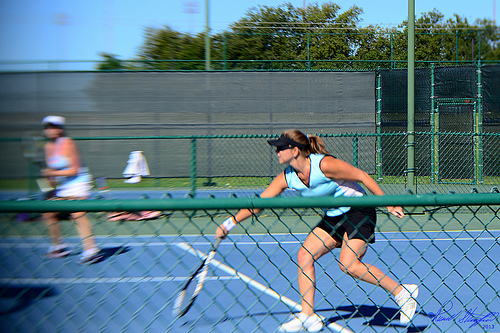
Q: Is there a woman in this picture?
A: Yes, there is a woman.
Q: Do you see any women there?
A: Yes, there is a woman.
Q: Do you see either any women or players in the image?
A: Yes, there is a woman.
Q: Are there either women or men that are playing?
A: Yes, the woman is playing.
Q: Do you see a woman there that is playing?
A: Yes, there is a woman that is playing.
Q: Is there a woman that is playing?
A: Yes, there is a woman that is playing.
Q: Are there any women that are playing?
A: Yes, there is a woman that is playing.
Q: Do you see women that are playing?
A: Yes, there is a woman that is playing.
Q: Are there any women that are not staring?
A: Yes, there is a woman that is playing.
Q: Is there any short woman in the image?
A: Yes, there is a short woman.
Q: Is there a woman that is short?
A: Yes, there is a woman that is short.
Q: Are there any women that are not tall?
A: Yes, there is a short woman.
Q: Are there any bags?
A: No, there are no bags.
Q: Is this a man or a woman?
A: This is a woman.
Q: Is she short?
A: Yes, the woman is short.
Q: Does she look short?
A: Yes, the woman is short.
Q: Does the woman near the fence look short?
A: Yes, the woman is short.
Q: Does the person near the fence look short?
A: Yes, the woman is short.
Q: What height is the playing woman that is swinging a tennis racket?
A: The woman is short.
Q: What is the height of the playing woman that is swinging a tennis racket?
A: The woman is short.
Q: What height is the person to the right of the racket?
A: The woman is short.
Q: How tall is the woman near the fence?
A: The woman is short.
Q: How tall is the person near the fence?
A: The woman is short.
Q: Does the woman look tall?
A: No, the woman is short.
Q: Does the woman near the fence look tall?
A: No, the woman is short.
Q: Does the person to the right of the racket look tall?
A: No, the woman is short.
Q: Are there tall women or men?
A: No, there is a woman but she is short.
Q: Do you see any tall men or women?
A: No, there is a woman but she is short.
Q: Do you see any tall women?
A: No, there is a woman but she is short.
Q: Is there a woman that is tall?
A: No, there is a woman but she is short.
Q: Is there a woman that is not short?
A: No, there is a woman but she is short.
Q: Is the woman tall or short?
A: The woman is short.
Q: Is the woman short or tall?
A: The woman is short.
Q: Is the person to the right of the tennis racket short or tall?
A: The woman is short.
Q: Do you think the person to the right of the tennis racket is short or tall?
A: The woman is short.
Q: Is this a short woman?
A: Yes, this is a short woman.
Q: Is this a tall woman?
A: No, this is a short woman.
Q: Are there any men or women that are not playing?
A: No, there is a woman but she is playing.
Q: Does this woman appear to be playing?
A: Yes, the woman is playing.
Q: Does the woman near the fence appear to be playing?
A: Yes, the woman is playing.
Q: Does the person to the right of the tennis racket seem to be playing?
A: Yes, the woman is playing.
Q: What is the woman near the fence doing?
A: The woman is playing.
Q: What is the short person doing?
A: The woman is playing.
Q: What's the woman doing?
A: The woman is playing.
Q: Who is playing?
A: The woman is playing.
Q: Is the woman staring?
A: No, the woman is playing.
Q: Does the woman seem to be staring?
A: No, the woman is playing.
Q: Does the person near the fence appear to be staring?
A: No, the woman is playing.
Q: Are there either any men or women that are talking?
A: No, there is a woman but she is playing.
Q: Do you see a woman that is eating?
A: No, there is a woman but she is playing.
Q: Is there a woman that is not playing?
A: No, there is a woman but she is playing.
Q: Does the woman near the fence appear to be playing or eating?
A: The woman is playing.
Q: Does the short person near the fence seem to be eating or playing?
A: The woman is playing.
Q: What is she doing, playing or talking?
A: The woman is playing.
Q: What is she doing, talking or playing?
A: The woman is playing.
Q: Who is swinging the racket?
A: The woman is swinging the racket.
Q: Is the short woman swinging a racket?
A: Yes, the woman is swinging a racket.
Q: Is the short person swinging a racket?
A: Yes, the woman is swinging a racket.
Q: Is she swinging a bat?
A: No, the woman is swinging a racket.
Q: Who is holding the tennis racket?
A: The woman is holding the tennis racket.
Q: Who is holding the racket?
A: The woman is holding the tennis racket.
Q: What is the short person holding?
A: The woman is holding the tennis racket.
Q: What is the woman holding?
A: The woman is holding the tennis racket.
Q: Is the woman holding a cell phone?
A: No, the woman is holding the racket.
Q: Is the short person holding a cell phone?
A: No, the woman is holding the racket.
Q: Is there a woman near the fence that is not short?
A: Yes, there is a woman near the fence.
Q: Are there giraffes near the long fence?
A: No, there is a woman near the fence.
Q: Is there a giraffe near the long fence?
A: No, there is a woman near the fence.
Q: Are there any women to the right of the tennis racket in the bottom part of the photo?
A: Yes, there is a woman to the right of the racket.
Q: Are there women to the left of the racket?
A: No, the woman is to the right of the racket.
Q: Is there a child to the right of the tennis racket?
A: No, there is a woman to the right of the tennis racket.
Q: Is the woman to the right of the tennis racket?
A: Yes, the woman is to the right of the tennis racket.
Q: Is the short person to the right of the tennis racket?
A: Yes, the woman is to the right of the tennis racket.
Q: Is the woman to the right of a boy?
A: No, the woman is to the right of the tennis racket.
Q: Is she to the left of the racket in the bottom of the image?
A: No, the woman is to the right of the tennis racket.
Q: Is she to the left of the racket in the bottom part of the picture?
A: No, the woman is to the right of the tennis racket.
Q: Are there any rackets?
A: Yes, there is a racket.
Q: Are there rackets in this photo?
A: Yes, there is a racket.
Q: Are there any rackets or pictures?
A: Yes, there is a racket.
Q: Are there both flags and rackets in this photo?
A: No, there is a racket but no flags.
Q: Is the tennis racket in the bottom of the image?
A: Yes, the tennis racket is in the bottom of the image.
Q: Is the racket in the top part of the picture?
A: No, the racket is in the bottom of the image.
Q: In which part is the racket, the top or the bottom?
A: The racket is in the bottom of the image.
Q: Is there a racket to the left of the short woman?
A: Yes, there is a racket to the left of the woman.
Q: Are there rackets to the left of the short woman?
A: Yes, there is a racket to the left of the woman.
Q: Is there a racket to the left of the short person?
A: Yes, there is a racket to the left of the woman.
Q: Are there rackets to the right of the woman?
A: No, the racket is to the left of the woman.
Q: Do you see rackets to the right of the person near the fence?
A: No, the racket is to the left of the woman.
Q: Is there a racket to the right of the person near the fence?
A: No, the racket is to the left of the woman.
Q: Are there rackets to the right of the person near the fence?
A: No, the racket is to the left of the woman.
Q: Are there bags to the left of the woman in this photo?
A: No, there is a racket to the left of the woman.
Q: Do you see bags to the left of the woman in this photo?
A: No, there is a racket to the left of the woman.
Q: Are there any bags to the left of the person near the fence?
A: No, there is a racket to the left of the woman.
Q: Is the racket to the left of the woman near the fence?
A: Yes, the racket is to the left of the woman.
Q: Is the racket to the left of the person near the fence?
A: Yes, the racket is to the left of the woman.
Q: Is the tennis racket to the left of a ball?
A: No, the tennis racket is to the left of the woman.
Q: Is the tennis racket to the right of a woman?
A: No, the tennis racket is to the left of a woman.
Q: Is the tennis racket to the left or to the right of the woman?
A: The tennis racket is to the left of the woman.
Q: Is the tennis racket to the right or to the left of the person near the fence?
A: The tennis racket is to the left of the woman.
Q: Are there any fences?
A: Yes, there is a fence.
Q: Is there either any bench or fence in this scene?
A: Yes, there is a fence.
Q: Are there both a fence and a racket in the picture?
A: Yes, there are both a fence and a racket.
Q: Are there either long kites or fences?
A: Yes, there is a long fence.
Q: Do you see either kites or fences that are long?
A: Yes, the fence is long.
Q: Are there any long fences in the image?
A: Yes, there is a long fence.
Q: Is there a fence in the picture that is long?
A: Yes, there is a fence that is long.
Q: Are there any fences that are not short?
A: Yes, there is a long fence.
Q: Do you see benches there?
A: No, there are no benches.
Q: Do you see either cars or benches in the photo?
A: No, there are no benches or cars.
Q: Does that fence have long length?
A: Yes, the fence is long.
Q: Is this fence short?
A: No, the fence is long.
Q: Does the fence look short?
A: No, the fence is long.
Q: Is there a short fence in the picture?
A: No, there is a fence but it is long.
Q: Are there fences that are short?
A: No, there is a fence but it is long.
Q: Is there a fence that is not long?
A: No, there is a fence but it is long.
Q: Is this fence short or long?
A: The fence is long.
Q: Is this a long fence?
A: Yes, this is a long fence.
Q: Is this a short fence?
A: No, this is a long fence.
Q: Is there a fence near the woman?
A: Yes, there is a fence near the woman.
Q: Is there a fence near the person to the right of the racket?
A: Yes, there is a fence near the woman.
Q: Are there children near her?
A: No, there is a fence near the woman.